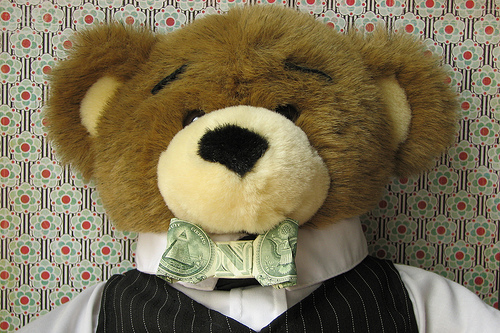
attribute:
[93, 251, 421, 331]
vest — pinstriped, multicolored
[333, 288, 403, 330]
vest — white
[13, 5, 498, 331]
teddy bear — brown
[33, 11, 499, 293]
bear — stuffed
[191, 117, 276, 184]
nose — black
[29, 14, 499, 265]
teddy bear — multicolored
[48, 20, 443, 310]
bear — fluffy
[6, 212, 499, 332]
undershirt — white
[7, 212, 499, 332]
teddybear — brown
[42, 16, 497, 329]
bear — brown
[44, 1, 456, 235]
teddy-bear's fur — multicolored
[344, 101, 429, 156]
ground — multicolored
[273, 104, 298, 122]
eye — plastic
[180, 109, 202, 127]
eye — plastic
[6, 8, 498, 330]
bear — brown, stuffed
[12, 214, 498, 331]
shirt — white